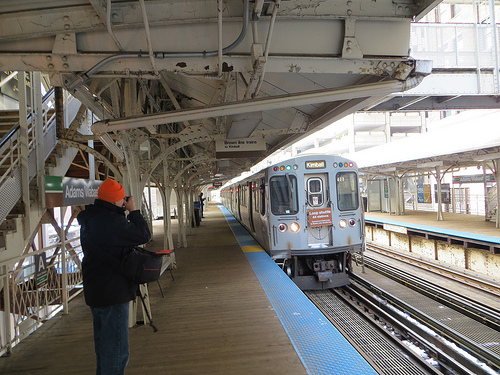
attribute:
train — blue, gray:
[219, 155, 366, 292]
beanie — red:
[98, 179, 123, 204]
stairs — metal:
[2, 71, 91, 301]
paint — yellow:
[238, 243, 268, 256]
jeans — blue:
[89, 302, 131, 374]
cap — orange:
[99, 178, 125, 202]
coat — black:
[77, 200, 151, 307]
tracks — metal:
[302, 267, 499, 374]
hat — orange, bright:
[99, 177, 126, 202]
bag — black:
[125, 245, 176, 287]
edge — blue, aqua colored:
[216, 204, 380, 375]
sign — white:
[215, 134, 266, 152]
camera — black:
[120, 194, 133, 210]